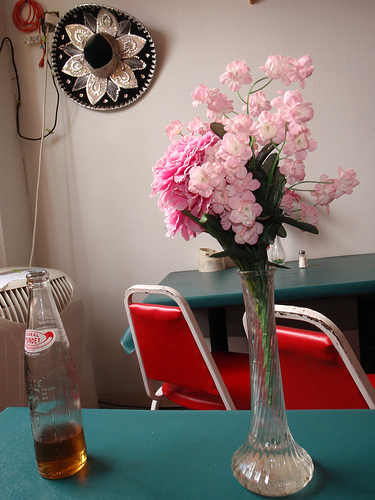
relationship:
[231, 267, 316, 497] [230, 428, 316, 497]
vase filled with water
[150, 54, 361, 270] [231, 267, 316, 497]
flowers inside a vase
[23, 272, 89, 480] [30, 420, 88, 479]
bottle of cola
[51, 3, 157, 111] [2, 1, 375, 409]
hat on wall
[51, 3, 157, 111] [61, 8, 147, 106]
hat with flower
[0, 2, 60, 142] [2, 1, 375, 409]
electrical wire hanging on wall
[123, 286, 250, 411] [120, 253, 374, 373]
chair at table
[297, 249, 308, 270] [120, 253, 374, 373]
salt shaker on top of table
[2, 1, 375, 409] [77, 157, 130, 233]
wall painted white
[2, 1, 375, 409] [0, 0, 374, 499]
wall in room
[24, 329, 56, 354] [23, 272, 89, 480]
label on bottle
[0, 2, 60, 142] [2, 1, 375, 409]
electrical wire along wall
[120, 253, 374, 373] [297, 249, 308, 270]
table with salt shaker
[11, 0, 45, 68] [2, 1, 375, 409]
cord on wall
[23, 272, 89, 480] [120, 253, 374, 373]
bottle on top of table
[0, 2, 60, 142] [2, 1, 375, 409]
electrical wire on wall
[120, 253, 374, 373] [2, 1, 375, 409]
table up against wall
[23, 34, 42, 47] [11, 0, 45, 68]
tag on a cord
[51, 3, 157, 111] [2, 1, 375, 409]
hat hanging on wall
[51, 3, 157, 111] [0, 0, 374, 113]
hat in background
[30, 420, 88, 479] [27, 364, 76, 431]
soda almost finished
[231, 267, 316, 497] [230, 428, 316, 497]
vase with water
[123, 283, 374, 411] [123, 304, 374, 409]
chairs have plastic cushions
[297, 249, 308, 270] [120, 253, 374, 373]
salt shaker on table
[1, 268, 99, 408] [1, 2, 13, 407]
heater in corner